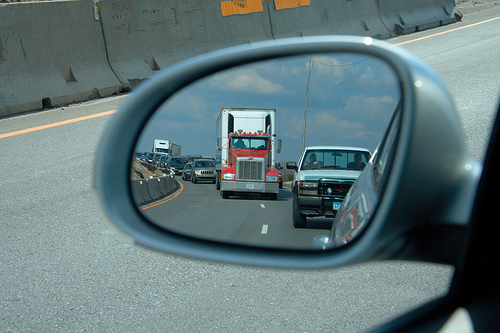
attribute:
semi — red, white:
[211, 105, 291, 198]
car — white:
[287, 136, 379, 231]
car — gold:
[193, 156, 220, 186]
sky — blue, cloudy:
[157, 52, 399, 144]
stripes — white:
[256, 215, 277, 239]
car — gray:
[138, 151, 152, 164]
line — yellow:
[0, 98, 130, 148]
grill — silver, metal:
[234, 158, 270, 185]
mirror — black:
[280, 156, 301, 175]